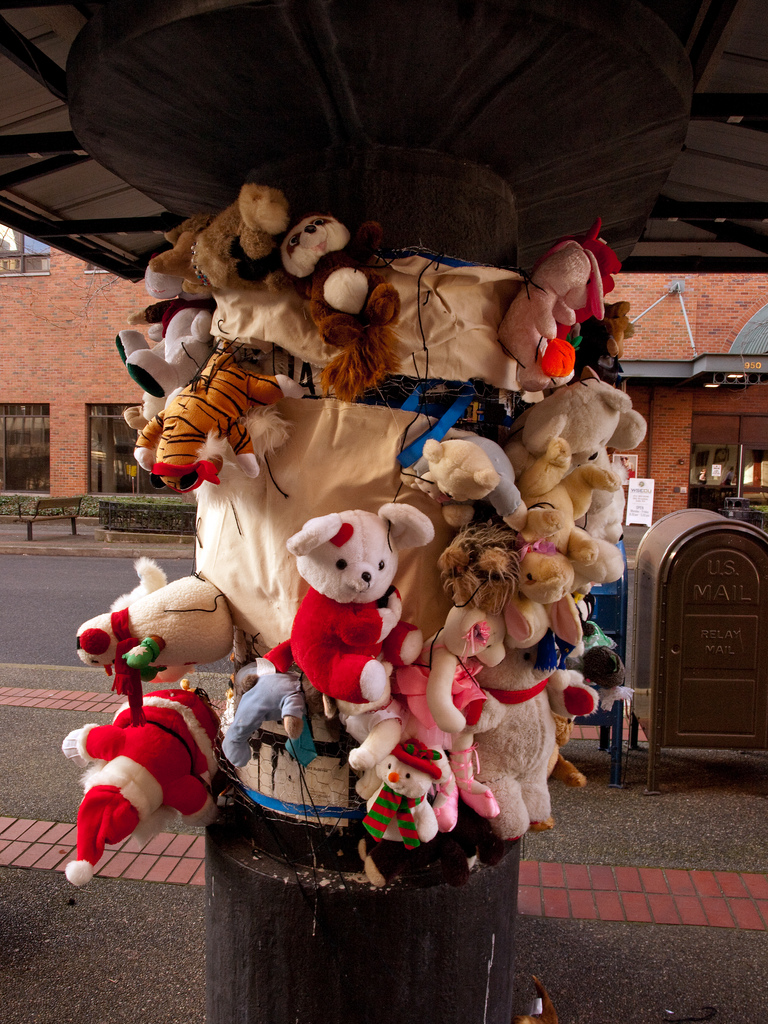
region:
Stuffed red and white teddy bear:
[281, 497, 433, 698]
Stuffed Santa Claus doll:
[61, 682, 231, 887]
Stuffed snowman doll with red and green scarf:
[364, 735, 444, 853]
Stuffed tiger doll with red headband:
[131, 347, 306, 492]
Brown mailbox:
[633, 508, 766, 797]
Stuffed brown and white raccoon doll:
[270, 207, 404, 403]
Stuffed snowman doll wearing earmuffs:
[72, 572, 236, 690]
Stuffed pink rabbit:
[491, 238, 609, 393]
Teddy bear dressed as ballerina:
[408, 592, 502, 835]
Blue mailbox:
[536, 521, 628, 788]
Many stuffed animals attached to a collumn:
[58, 184, 646, 881]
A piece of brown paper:
[194, 397, 474, 666]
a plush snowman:
[357, 734, 438, 851]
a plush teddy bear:
[262, 499, 433, 705]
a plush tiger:
[133, 336, 300, 493]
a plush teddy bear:
[398, 434, 526, 532]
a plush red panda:
[268, 212, 401, 398]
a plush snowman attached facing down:
[72, 578, 236, 726]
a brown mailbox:
[624, 506, 765, 794]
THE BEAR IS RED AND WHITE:
[255, 495, 440, 715]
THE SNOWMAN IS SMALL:
[346, 727, 453, 875]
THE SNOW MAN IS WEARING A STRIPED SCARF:
[351, 778, 431, 854]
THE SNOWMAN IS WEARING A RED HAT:
[385, 723, 454, 785]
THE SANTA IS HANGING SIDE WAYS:
[35, 674, 239, 918]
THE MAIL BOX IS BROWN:
[588, 477, 764, 812]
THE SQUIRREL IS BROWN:
[261, 205, 414, 404]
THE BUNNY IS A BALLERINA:
[391, 580, 524, 837]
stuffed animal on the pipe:
[362, 744, 414, 839]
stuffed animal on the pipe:
[433, 744, 496, 852]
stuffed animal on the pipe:
[471, 688, 554, 841]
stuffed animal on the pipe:
[231, 667, 296, 738]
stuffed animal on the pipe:
[195, 386, 314, 470]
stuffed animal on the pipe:
[505, 248, 593, 382]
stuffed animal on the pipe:
[142, 366, 238, 465]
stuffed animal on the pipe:
[299, 209, 380, 337]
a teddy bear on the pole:
[296, 478, 432, 661]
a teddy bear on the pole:
[369, 742, 438, 850]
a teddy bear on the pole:
[228, 646, 313, 779]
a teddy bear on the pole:
[54, 688, 284, 872]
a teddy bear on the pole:
[93, 579, 234, 694]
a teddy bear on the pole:
[421, 609, 507, 771]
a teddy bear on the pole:
[458, 652, 609, 824]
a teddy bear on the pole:
[469, 538, 596, 630]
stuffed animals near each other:
[43, 228, 687, 869]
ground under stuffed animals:
[31, 914, 178, 1016]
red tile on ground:
[578, 813, 730, 949]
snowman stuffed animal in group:
[319, 737, 466, 881]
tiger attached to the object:
[110, 330, 307, 532]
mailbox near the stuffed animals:
[609, 502, 766, 766]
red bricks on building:
[4, 279, 136, 402]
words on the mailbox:
[662, 533, 762, 631]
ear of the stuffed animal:
[256, 499, 361, 582]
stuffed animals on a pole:
[65, 151, 656, 1022]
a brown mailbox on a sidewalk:
[623, 504, 766, 814]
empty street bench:
[4, 486, 93, 545]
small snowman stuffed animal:
[360, 738, 443, 844]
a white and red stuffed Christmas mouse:
[265, 499, 433, 706]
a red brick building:
[2, 228, 166, 519]